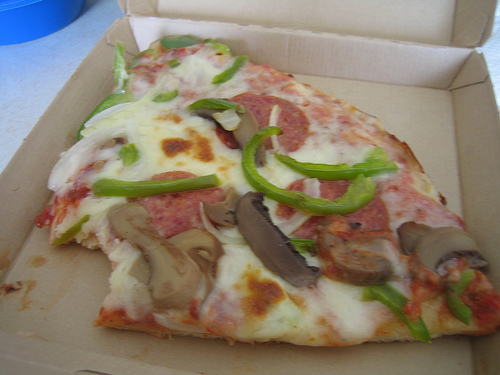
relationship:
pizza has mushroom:
[26, 30, 499, 353] [195, 97, 270, 170]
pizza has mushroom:
[26, 30, 499, 353] [197, 185, 245, 227]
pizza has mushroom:
[26, 30, 499, 353] [105, 198, 231, 317]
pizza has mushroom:
[26, 30, 499, 353] [232, 188, 323, 290]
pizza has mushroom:
[26, 30, 499, 353] [393, 216, 494, 284]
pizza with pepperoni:
[26, 30, 499, 353] [273, 172, 393, 250]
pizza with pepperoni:
[26, 30, 499, 353] [213, 88, 314, 157]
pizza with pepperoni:
[26, 30, 499, 353] [124, 167, 228, 244]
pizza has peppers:
[26, 30, 499, 353] [356, 275, 438, 349]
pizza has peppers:
[26, 30, 499, 353] [88, 172, 223, 199]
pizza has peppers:
[26, 30, 499, 353] [238, 122, 380, 219]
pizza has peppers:
[26, 30, 499, 353] [270, 143, 403, 183]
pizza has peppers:
[26, 30, 499, 353] [210, 51, 252, 87]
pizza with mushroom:
[26, 30, 499, 353] [195, 97, 270, 170]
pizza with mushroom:
[26, 30, 499, 353] [105, 198, 231, 317]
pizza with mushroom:
[26, 30, 499, 353] [197, 185, 245, 227]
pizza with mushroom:
[26, 30, 499, 353] [232, 188, 323, 290]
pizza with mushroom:
[26, 30, 499, 353] [393, 216, 494, 284]